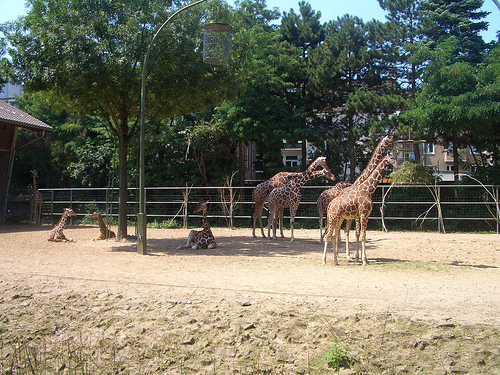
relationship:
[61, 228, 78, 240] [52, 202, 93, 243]
leg of giraffe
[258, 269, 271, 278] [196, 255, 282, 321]
dirt on ground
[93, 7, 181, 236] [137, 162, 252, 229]
tree on fence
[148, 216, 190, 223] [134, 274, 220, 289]
grass on sand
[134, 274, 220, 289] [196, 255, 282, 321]
sand on ground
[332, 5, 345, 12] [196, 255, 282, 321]
ligh in ground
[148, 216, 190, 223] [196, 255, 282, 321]
grass on ground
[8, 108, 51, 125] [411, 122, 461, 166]
roof on building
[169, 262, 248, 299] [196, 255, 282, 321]
part of ground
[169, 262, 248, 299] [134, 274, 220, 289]
part of sand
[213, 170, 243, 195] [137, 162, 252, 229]
part of fence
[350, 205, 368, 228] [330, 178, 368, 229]
part of stomach